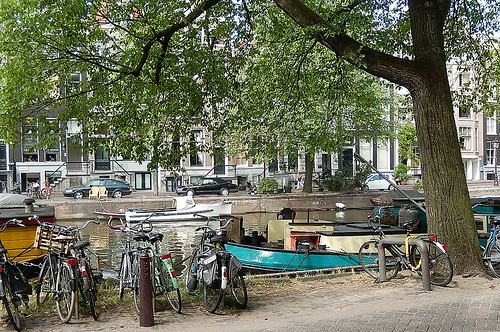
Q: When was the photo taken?
A: Daytime.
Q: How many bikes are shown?
A: Nine.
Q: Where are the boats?
A: In the canal.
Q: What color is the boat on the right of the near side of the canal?
A: Blue.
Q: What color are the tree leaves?
A: Green.